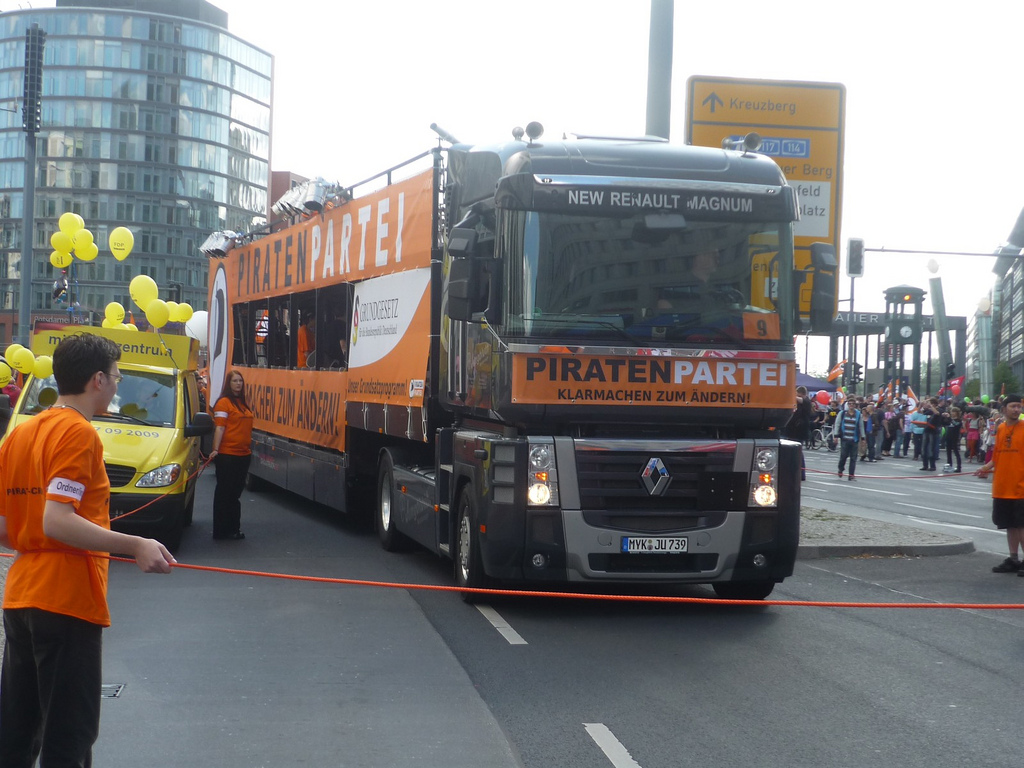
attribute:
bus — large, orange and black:
[198, 119, 805, 598]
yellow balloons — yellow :
[36, 207, 100, 274]